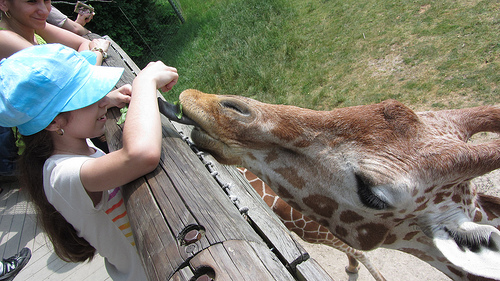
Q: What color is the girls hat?
A: Blue.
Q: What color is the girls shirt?
A: White.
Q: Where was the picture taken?
A: At the zoo.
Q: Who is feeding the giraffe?
A: A girl.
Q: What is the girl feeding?
A: A giraffe.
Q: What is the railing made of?
A: Wood.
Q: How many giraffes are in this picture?
A: One.